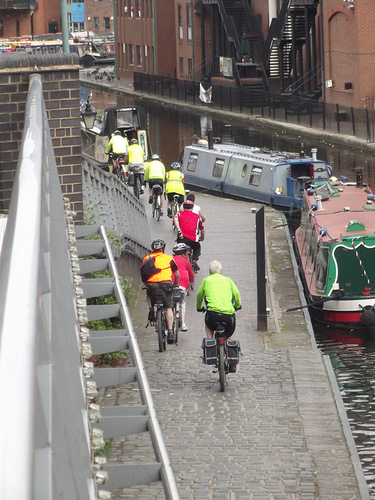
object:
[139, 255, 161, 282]
bags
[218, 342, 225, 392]
bike tire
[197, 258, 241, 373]
bike rider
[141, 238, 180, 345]
bike rider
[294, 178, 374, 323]
boat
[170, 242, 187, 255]
helmet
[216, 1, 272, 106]
staircase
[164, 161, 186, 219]
person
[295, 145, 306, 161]
ground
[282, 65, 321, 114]
stairs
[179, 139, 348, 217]
blue boat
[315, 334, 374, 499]
water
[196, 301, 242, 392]
bike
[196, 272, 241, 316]
jacket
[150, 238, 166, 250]
helmet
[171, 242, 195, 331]
person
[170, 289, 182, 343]
bike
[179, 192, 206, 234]
rider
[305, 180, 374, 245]
roof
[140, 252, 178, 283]
orange shirt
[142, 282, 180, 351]
bike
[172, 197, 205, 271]
man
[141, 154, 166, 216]
man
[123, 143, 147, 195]
man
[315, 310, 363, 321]
stripe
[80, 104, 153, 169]
boat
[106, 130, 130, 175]
person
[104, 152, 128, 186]
bike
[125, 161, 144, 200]
bike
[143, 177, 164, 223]
bike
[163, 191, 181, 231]
bike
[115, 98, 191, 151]
water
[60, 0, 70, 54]
pole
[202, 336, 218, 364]
bag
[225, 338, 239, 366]
bag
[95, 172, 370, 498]
sidewalk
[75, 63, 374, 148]
sidewalk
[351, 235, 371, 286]
decoration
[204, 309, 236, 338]
shorts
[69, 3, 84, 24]
sign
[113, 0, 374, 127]
building